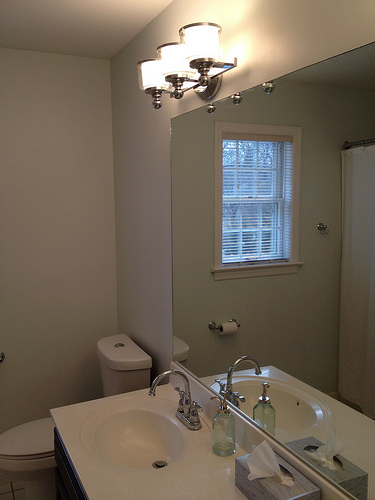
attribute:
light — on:
[183, 22, 235, 85]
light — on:
[156, 40, 187, 99]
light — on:
[138, 57, 165, 109]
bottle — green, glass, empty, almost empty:
[209, 393, 238, 458]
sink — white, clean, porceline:
[49, 361, 375, 498]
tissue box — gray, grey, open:
[236, 440, 320, 500]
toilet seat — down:
[1, 414, 57, 455]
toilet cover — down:
[1, 415, 57, 455]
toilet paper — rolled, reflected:
[207, 318, 241, 338]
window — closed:
[212, 119, 304, 282]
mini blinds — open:
[223, 138, 286, 262]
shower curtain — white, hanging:
[338, 145, 375, 414]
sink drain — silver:
[153, 460, 169, 470]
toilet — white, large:
[1, 333, 153, 499]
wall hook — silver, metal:
[316, 221, 332, 237]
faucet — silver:
[149, 368, 204, 433]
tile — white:
[2, 479, 26, 500]